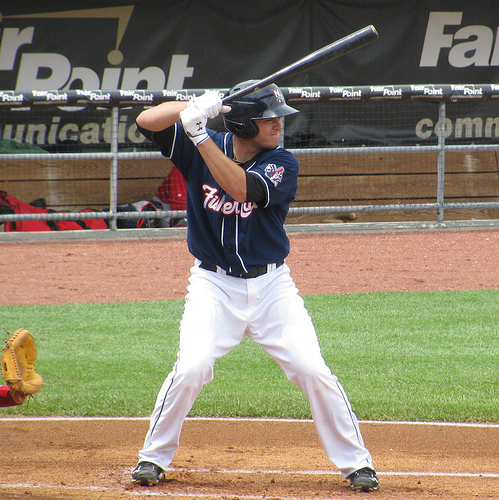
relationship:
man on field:
[134, 24, 381, 495] [1, 227, 497, 497]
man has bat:
[134, 24, 381, 495] [218, 22, 379, 112]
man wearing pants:
[134, 24, 381, 495] [136, 253, 376, 477]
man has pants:
[134, 24, 381, 495] [136, 253, 376, 477]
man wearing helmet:
[134, 24, 381, 495] [222, 79, 299, 140]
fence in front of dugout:
[2, 82, 497, 238] [3, 0, 498, 234]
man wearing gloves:
[134, 24, 381, 495] [180, 110, 210, 146]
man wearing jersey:
[134, 24, 381, 495] [165, 124, 299, 266]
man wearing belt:
[134, 24, 381, 495] [196, 260, 286, 282]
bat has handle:
[218, 22, 379, 112] [222, 90, 249, 108]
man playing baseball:
[134, 24, 381, 495] [144, 24, 385, 138]